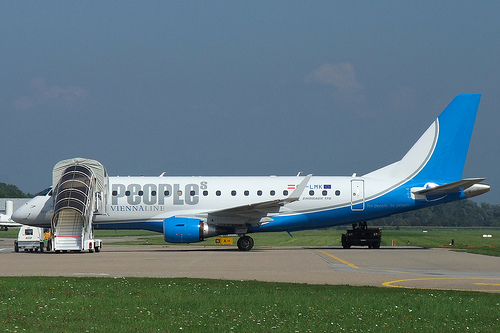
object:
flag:
[288, 184, 295, 188]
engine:
[163, 215, 205, 243]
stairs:
[55, 209, 83, 250]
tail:
[360, 93, 482, 181]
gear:
[237, 236, 255, 251]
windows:
[112, 190, 341, 196]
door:
[352, 181, 364, 209]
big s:
[200, 181, 207, 189]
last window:
[335, 190, 340, 196]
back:
[361, 93, 490, 221]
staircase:
[51, 157, 110, 253]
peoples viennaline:
[111, 181, 207, 211]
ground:
[0, 234, 500, 293]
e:
[127, 184, 141, 205]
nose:
[11, 196, 37, 227]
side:
[107, 176, 361, 243]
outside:
[0, 225, 500, 333]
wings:
[198, 174, 312, 227]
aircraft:
[12, 93, 491, 252]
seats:
[112, 190, 249, 196]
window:
[125, 191, 130, 196]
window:
[164, 191, 169, 196]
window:
[190, 190, 196, 195]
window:
[231, 190, 237, 196]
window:
[257, 190, 262, 196]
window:
[138, 191, 144, 196]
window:
[203, 191, 208, 196]